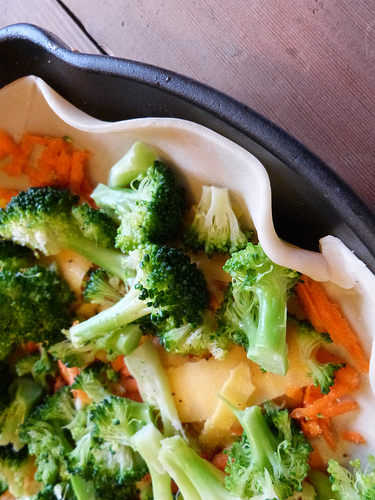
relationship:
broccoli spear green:
[80, 164, 188, 245] [142, 200, 158, 212]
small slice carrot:
[326, 300, 330, 318] [299, 283, 369, 370]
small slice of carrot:
[326, 300, 330, 318] [299, 283, 369, 370]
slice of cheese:
[214, 362, 254, 409] [166, 355, 311, 419]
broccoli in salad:
[80, 164, 188, 245] [2, 153, 220, 498]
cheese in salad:
[166, 355, 311, 419] [2, 153, 220, 498]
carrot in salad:
[299, 283, 369, 370] [2, 153, 220, 498]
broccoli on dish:
[80, 164, 188, 245] [7, 12, 369, 463]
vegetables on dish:
[19, 134, 183, 300] [7, 12, 369, 463]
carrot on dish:
[299, 283, 369, 370] [7, 12, 369, 463]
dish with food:
[7, 12, 369, 463] [8, 276, 297, 498]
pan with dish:
[57, 17, 193, 99] [7, 12, 369, 463]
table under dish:
[197, 3, 359, 59] [7, 12, 369, 463]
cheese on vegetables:
[166, 355, 311, 419] [19, 134, 183, 300]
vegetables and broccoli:
[19, 134, 183, 300] [80, 164, 188, 245]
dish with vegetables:
[17, 60, 372, 337] [19, 134, 183, 300]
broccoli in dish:
[80, 164, 188, 245] [17, 60, 372, 337]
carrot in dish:
[299, 283, 369, 370] [17, 60, 372, 337]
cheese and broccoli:
[166, 355, 311, 419] [80, 164, 188, 245]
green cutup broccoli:
[142, 200, 158, 212] [80, 164, 188, 245]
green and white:
[142, 200, 158, 212] [184, 137, 217, 167]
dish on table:
[17, 60, 372, 337] [197, 3, 359, 59]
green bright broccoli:
[142, 200, 158, 212] [80, 164, 188, 245]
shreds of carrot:
[300, 394, 347, 436] [299, 283, 369, 370]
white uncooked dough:
[184, 137, 217, 167] [242, 376, 268, 395]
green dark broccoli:
[142, 200, 158, 212] [80, 164, 188, 245]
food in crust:
[8, 276, 297, 498] [24, 76, 90, 126]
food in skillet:
[8, 276, 297, 498] [48, 39, 132, 81]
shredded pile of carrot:
[28, 132, 91, 177] [299, 283, 369, 370]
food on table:
[8, 276, 297, 498] [197, 3, 359, 59]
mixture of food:
[66, 291, 264, 431] [8, 276, 297, 498]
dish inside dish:
[17, 60, 372, 337] [17, 60, 372, 337]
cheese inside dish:
[166, 355, 311, 419] [7, 12, 369, 463]